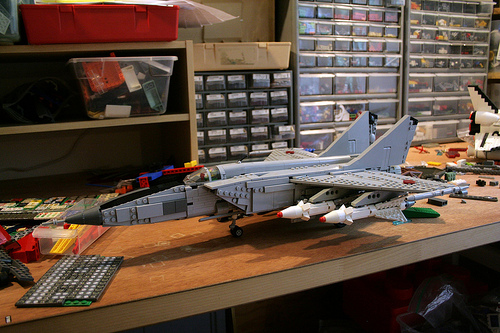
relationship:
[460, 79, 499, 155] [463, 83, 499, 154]
tail of airplane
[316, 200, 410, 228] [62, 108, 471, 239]
missle on plane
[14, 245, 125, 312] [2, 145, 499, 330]
lego on table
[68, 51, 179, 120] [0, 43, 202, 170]
box on shelf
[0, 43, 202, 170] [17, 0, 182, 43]
shelf with container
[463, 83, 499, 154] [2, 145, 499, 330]
airplane on table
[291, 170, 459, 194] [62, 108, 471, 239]
wing on plane